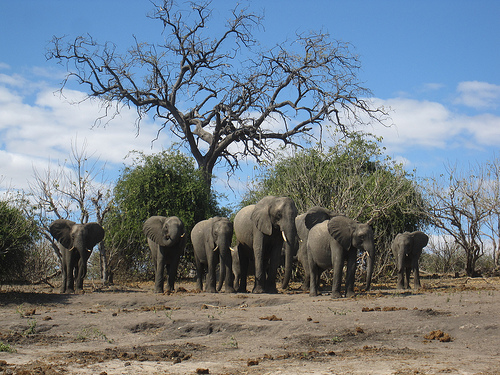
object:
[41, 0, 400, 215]
tree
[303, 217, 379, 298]
elephants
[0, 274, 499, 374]
ground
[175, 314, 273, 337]
hills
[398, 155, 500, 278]
tree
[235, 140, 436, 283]
trees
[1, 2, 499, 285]
background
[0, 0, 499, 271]
sky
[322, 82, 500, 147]
clouds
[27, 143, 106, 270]
tree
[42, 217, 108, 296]
elephant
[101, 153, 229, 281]
tree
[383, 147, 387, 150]
leaves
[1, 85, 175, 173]
cloud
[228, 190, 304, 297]
elephant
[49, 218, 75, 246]
ear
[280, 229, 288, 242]
tusk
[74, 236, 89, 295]
nose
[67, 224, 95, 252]
head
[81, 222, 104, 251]
ears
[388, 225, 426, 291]
elephant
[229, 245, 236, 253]
tusks